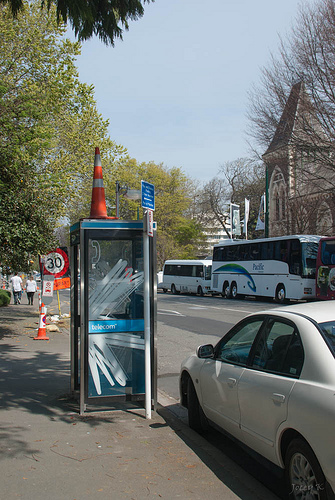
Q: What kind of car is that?
A: It is a Toyota.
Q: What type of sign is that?
A: It is a road sign.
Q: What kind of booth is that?
A: It is a telephone booth.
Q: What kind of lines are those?
A: Those are white lines.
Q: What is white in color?
A: A car.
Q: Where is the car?
A: On the street.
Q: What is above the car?
A: The sky.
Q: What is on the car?
A: Door handle.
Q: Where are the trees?
A: Next to the car.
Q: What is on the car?
A: Windows.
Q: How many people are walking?
A: Two.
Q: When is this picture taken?
A: Day time.